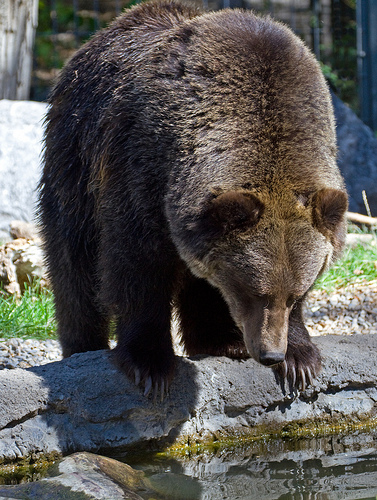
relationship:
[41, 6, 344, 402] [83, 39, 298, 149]
bear has fur